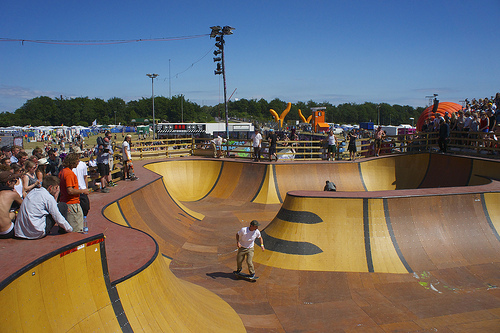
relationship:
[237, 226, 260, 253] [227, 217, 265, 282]
t shirt of skate boarder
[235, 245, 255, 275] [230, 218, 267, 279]
pants of skate boarder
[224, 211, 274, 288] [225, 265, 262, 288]
man riding skateboard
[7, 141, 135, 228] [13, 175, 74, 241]
people watching man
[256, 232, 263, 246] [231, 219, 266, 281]
arm of man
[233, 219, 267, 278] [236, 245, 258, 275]
man wearing pants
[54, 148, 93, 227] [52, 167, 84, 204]
man wearing shirt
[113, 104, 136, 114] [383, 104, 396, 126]
leaves on tree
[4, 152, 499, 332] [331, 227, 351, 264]
ramp painted yellow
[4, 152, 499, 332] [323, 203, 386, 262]
ramp painted yellow painted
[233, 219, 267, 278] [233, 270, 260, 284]
man riding on skateboard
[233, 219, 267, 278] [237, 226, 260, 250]
man wearing t shirt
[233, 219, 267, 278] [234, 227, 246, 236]
man wearing sleeve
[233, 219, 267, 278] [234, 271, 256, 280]
man on a skateboard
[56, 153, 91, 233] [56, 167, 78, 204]
man wearing a shirt